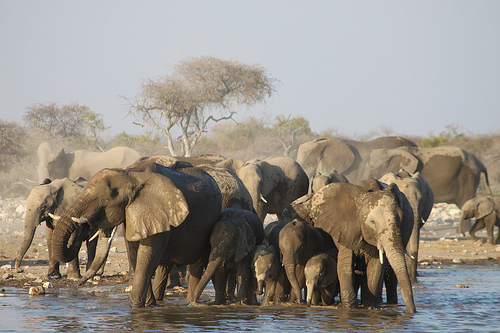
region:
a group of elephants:
[26, 104, 448, 331]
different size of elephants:
[37, 128, 400, 331]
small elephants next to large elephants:
[151, 149, 393, 331]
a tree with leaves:
[100, 27, 294, 167]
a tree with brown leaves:
[134, 27, 274, 129]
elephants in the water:
[22, 96, 432, 331]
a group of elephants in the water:
[32, 109, 457, 331]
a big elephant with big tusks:
[37, 120, 344, 323]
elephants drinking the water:
[10, 84, 377, 329]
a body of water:
[428, 292, 474, 330]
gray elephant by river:
[6, 176, 61, 214]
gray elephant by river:
[48, 165, 196, 287]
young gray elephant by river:
[197, 202, 251, 299]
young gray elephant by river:
[266, 212, 306, 297]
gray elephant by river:
[325, 175, 408, 302]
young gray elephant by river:
[459, 195, 497, 247]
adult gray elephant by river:
[304, 132, 416, 171]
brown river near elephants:
[17, 285, 117, 327]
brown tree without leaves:
[147, 53, 261, 148]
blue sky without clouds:
[271, 3, 484, 103]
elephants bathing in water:
[35, 123, 410, 324]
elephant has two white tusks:
[42, 154, 84, 240]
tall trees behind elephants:
[112, 30, 289, 163]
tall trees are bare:
[122, 42, 259, 165]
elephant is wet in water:
[298, 160, 433, 315]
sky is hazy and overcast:
[288, 6, 456, 121]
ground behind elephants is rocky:
[17, 211, 172, 278]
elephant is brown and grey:
[72, 164, 211, 300]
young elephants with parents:
[197, 223, 314, 312]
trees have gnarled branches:
[111, 57, 253, 159]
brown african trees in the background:
[18, 61, 298, 156]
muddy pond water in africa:
[57, 295, 337, 330]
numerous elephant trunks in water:
[125, 227, 485, 302]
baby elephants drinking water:
[195, 225, 341, 316]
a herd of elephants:
[25, 125, 485, 315]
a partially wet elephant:
[390, 140, 482, 197]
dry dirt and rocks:
[427, 220, 463, 256]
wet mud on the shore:
[438, 256, 495, 264]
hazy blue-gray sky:
[17, 36, 122, 81]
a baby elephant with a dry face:
[299, 260, 334, 312]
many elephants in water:
[44, 163, 430, 313]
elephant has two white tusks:
[39, 191, 81, 237]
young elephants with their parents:
[196, 196, 341, 313]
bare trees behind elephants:
[149, 37, 261, 160]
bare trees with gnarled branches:
[106, 52, 288, 157]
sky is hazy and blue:
[277, 9, 498, 138]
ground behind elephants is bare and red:
[335, 216, 499, 281]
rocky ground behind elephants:
[5, 176, 127, 282]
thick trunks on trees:
[131, 107, 201, 159]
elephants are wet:
[100, 147, 415, 304]